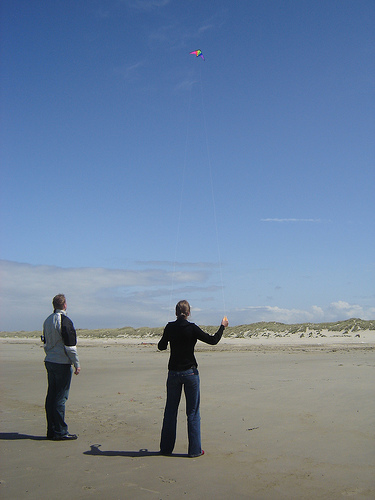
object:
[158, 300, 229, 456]
lady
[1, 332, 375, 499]
sand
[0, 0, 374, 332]
clouds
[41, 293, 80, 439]
ocean waves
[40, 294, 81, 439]
man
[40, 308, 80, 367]
coat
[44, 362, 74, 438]
jeans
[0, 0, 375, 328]
blue sky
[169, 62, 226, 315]
string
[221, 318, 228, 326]
hand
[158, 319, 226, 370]
black shirt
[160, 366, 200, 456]
blue jeans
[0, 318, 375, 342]
sand dunes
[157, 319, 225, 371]
sweater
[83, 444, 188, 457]
shadow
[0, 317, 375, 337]
grass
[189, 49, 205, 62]
kite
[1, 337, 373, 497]
beach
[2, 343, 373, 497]
ground